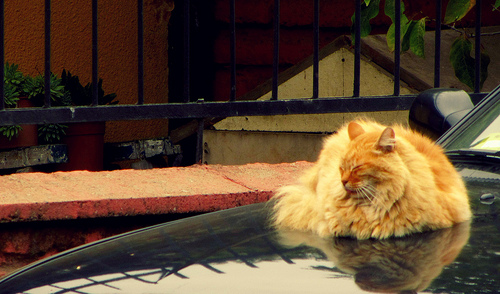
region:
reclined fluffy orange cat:
[265, 107, 475, 251]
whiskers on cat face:
[348, 182, 394, 218]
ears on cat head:
[343, 119, 398, 153]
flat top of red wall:
[30, 160, 293, 221]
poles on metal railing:
[55, 19, 304, 132]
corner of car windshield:
[441, 104, 498, 166]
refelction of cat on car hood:
[376, 228, 480, 290]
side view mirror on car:
[398, 79, 480, 146]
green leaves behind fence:
[363, 8, 453, 60]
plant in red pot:
[53, 65, 119, 165]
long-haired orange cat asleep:
[274, 117, 469, 237]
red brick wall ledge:
[0, 164, 327, 241]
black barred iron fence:
[1, 1, 496, 110]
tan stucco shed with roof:
[197, 25, 492, 160]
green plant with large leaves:
[344, 0, 496, 86]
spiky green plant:
[1, 62, 116, 139]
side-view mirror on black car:
[414, 86, 498, 291]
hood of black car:
[0, 200, 497, 292]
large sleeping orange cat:
[274, 119, 474, 244]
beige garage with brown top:
[202, 31, 497, 161]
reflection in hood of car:
[76, 247, 262, 279]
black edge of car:
[128, 217, 204, 242]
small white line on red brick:
[77, 206, 118, 218]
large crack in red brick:
[203, 155, 260, 198]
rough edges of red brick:
[201, 157, 280, 172]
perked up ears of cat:
[367, 124, 408, 155]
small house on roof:
[333, 48, 354, 75]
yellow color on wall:
[228, 117, 317, 147]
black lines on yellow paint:
[276, 37, 443, 99]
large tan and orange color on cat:
[260, 102, 469, 262]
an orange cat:
[303, 107, 464, 255]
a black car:
[3, 98, 498, 292]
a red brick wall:
[13, 163, 318, 270]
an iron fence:
[18, 5, 475, 137]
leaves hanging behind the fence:
[332, 5, 474, 54]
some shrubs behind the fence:
[0, 67, 149, 149]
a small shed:
[182, 27, 487, 159]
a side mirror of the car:
[400, 70, 475, 133]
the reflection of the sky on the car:
[54, 258, 388, 292]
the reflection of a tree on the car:
[406, 225, 496, 292]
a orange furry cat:
[243, 101, 472, 255]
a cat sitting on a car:
[254, 101, 474, 292]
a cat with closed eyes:
[316, 115, 401, 195]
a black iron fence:
[64, 39, 419, 143]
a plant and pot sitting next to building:
[47, 60, 121, 172]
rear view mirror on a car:
[402, 81, 474, 148]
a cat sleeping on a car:
[222, 119, 489, 273]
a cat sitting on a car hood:
[206, 94, 471, 284]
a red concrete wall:
[1, 142, 263, 242]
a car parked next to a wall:
[0, 69, 495, 289]